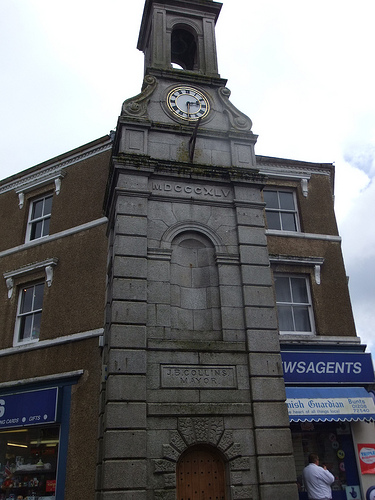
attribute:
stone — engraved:
[160, 364, 239, 389]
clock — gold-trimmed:
[163, 83, 212, 125]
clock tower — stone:
[116, 2, 259, 157]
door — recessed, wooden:
[175, 442, 235, 498]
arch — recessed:
[166, 231, 222, 341]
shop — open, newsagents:
[280, 347, 374, 500]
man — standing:
[301, 454, 335, 499]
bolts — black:
[226, 480, 231, 492]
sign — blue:
[0, 384, 62, 431]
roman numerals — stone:
[152, 181, 235, 204]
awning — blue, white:
[278, 386, 374, 424]